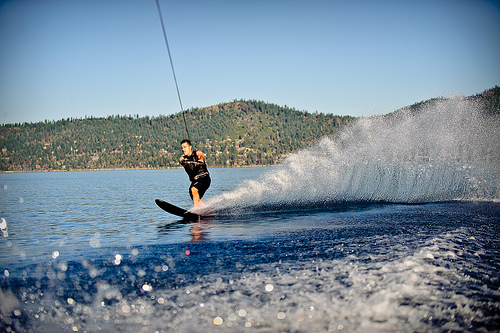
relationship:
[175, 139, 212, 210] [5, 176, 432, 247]
man water skiing in lake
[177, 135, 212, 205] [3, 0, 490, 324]
man skiing in water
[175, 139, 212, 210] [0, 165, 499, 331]
man skiing in water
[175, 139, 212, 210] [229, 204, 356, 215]
man making wave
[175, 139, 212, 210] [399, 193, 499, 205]
man making wave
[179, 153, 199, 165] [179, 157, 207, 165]
handle in hands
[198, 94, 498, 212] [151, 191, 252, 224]
water splashing from water ski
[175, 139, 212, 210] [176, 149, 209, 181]
man wearing life jacket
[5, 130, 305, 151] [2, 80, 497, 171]
trees on hills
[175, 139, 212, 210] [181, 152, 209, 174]
man wearing life jacket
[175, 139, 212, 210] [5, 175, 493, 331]
man skiing on water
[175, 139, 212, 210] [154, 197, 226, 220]
man stands on ski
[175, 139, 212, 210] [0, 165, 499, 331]
man cable skiing in water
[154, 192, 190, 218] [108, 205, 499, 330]
ski in water